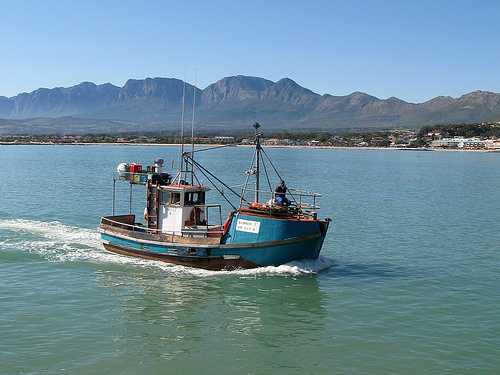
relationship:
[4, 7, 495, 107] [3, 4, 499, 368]
sunny day photo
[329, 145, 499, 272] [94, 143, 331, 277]
no boats sailing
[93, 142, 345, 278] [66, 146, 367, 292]
turquoise small boat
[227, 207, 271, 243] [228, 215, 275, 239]
white sign visible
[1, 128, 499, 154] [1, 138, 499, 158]
buildings along coastline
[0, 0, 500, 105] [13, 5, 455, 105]
sky blue sky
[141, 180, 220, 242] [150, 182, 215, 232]
white visible cabin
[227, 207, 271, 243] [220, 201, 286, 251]
white board visible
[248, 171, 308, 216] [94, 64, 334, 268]
person in boat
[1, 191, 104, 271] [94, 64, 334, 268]
waves behind boat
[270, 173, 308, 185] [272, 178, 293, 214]
head of person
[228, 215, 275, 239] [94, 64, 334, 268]
sign on boat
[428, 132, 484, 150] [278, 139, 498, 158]
building on beach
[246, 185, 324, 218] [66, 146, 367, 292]
railing on top of boat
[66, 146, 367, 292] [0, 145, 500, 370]
boat traveling in sea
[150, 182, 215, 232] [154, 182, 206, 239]
cabin in boat